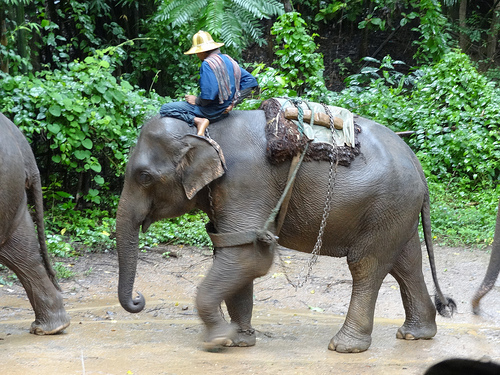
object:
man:
[160, 30, 258, 139]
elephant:
[114, 97, 457, 355]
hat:
[180, 30, 225, 54]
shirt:
[192, 52, 256, 117]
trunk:
[113, 192, 151, 314]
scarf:
[205, 53, 243, 104]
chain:
[275, 102, 337, 289]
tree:
[151, 2, 285, 50]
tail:
[421, 175, 457, 322]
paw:
[199, 322, 245, 353]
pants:
[157, 104, 227, 125]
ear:
[172, 133, 227, 200]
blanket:
[261, 97, 360, 167]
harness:
[205, 153, 305, 257]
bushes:
[0, 2, 499, 250]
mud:
[0, 242, 499, 375]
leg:
[0, 204, 71, 336]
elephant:
[0, 113, 70, 336]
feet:
[192, 230, 274, 351]